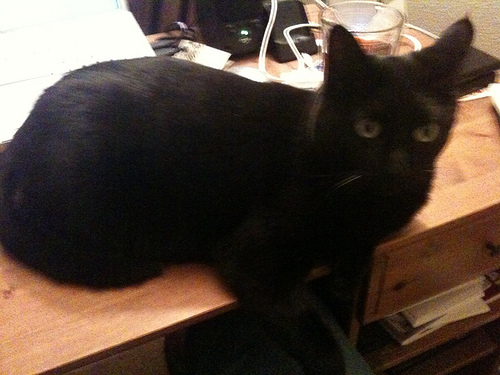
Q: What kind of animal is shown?
A: Cat.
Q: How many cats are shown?
A: One.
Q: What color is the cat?
A: Black.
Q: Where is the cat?
A: Desk.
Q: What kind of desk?
A: Wood.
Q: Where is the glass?
A: Behind the cat.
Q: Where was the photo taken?
A: At a desk.